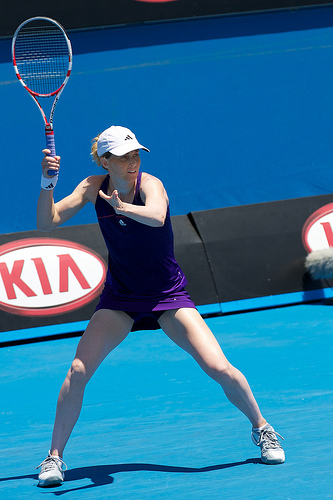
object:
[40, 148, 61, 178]
hand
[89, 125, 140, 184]
head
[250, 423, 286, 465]
shoe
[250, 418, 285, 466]
foot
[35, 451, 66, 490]
foot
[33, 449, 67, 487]
shoe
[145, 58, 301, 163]
wall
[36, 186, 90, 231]
arm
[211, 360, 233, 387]
knee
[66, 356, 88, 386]
knee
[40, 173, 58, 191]
band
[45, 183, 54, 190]
logo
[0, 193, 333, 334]
barrier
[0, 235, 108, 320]
logo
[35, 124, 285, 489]
player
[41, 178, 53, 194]
wrist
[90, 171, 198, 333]
suit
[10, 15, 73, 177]
racket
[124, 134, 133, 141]
logo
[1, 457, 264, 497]
shadow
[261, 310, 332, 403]
court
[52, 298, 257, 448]
legs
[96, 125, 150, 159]
hat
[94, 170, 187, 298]
gear